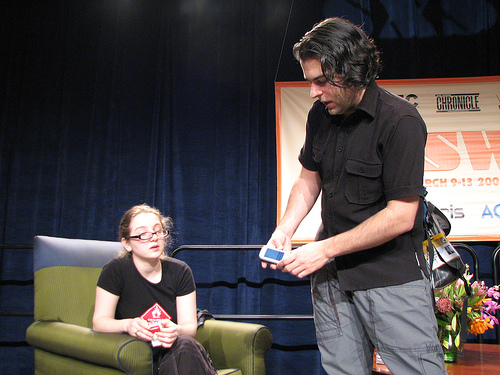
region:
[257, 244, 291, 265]
White cell phone with blue screen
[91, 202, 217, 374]
Girl holding a red card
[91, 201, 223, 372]
Girl sitting in a green chair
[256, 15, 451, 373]
Man looking at a cell phone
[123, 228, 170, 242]
Eye glasses with a thick black frame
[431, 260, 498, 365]
Vase full of mixed flowers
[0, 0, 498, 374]
Dark blue curtain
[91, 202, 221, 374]
Girl with dirty blonde hair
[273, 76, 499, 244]
Large sign with orange border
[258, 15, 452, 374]
Man wearing grey cargo pants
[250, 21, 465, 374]
A man holding a cell phone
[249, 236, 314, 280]
a phone in a man's hand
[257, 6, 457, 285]
A man wearing a black shirt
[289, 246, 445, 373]
A man wearing gray pants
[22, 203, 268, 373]
A girl sitting in a chair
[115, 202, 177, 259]
A girl wearing glasses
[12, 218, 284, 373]
A green chair with a gray stripe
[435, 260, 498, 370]
Flowers behind the man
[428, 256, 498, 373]
Flowers on a table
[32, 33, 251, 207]
A large blue curtain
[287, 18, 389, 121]
Wavy black hair on young man's face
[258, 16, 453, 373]
Young man demonstrating something on his cell phone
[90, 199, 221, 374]
Young lady with red hair looking at man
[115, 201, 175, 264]
Red haired lady with glasses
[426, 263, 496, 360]
Vase of orange and pink flowers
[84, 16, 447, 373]
Two young people looking at cell phone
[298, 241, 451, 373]
Gray cargo pants on young man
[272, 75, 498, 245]
Orange billboad behind young man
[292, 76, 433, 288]
Black collared shirt with pockets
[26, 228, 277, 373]
Green sofa with young lady sitting on it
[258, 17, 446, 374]
man in black shirt holding a phone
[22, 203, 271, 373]
woman wearing glasses sitting in chair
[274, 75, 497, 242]
white sign with orange trim behind the man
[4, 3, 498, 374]
dark blue curtains in the background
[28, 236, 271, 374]
green chair the woman is sitting on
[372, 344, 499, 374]
brown table behind the man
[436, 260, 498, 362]
vase of flowers on the table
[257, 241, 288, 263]
phone the man is holding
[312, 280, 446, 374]
gray pants man is wearing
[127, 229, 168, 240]
glasses worn by the woman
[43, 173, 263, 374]
a girl sitting down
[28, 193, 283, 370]
a girl sitting in a green chair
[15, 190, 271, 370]
a girl sitting in a green and blue chair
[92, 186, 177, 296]
a girl with curly hair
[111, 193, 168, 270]
a girl wearing glasses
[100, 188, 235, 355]
a girl wearing a shirt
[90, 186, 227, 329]
a girl wearing a black shirt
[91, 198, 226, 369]
a girl holding a trophy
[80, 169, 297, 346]
a girl holding a red trophy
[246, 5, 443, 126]
a man with long hair